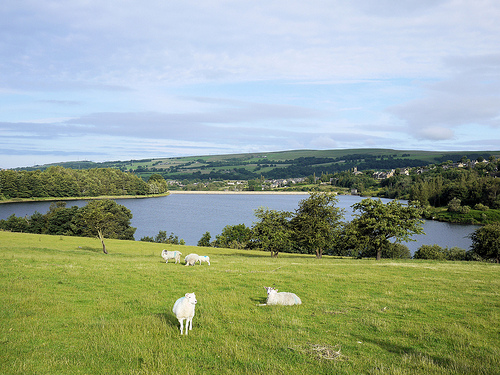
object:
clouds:
[0, 0, 498, 158]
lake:
[0, 192, 488, 259]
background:
[0, 0, 498, 374]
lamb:
[170, 290, 198, 337]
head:
[184, 292, 197, 305]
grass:
[0, 228, 496, 374]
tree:
[289, 184, 348, 258]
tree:
[248, 207, 295, 258]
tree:
[70, 197, 132, 255]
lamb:
[256, 284, 304, 308]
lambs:
[158, 248, 184, 265]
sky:
[0, 0, 499, 170]